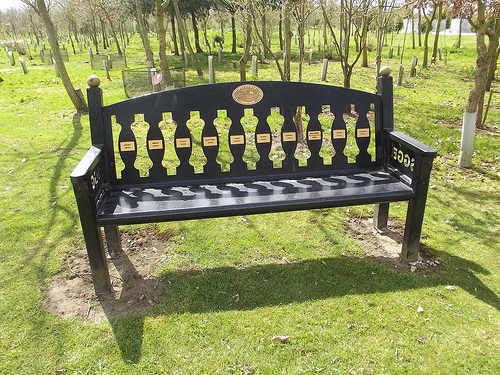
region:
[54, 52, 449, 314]
a bench on a field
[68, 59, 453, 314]
bench is black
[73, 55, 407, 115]
bench has two balls on restback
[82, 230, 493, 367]
shadow of a bench on the grass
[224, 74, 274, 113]
a plaque on top of restback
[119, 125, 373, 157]
small plaques on bench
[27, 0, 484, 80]
plants behind a bench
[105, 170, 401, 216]
shadows on bench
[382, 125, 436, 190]
right armrest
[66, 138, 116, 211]
right armrest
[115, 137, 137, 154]
plague on the bench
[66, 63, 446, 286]
bench with plagues on it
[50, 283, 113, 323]
patch of dirt on the ground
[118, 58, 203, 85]
fence around the tree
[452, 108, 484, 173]
white tube around tree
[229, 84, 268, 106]
gold plague on the bench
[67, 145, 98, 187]
arm of the bench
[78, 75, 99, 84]
white knob on the bench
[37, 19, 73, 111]
tree trunk attached to the tree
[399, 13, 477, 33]
white fence in the background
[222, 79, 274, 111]
A label on a bench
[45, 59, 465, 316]
a wooden bench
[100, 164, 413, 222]
the seating area of the bench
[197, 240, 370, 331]
grass below the bench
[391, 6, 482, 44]
a wooden structure in the background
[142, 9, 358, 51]
some trees in the background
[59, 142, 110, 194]
the right arm of the bench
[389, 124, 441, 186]
the left arm of the bench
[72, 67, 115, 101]
a decorative wooden ball atop the bench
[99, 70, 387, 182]
the back of the bench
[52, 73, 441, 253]
black wooden bench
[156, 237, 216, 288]
short green and brown grass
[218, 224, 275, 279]
short green and brown grass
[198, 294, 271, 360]
short green and brown grass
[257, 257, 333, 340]
short green and brown grass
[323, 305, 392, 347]
short green and brown grass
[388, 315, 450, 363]
short green and brown grass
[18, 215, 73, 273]
short green and brown grass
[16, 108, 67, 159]
short green and brown grass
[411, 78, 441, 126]
short green and brown grass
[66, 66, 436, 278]
a black bench in the park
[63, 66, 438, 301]
a black and gold bench in the park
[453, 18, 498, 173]
a brown tree trunk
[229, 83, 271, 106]
a gold symbol on the bench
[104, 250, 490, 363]
a shadow under the bench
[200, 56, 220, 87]
white concrete post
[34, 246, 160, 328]
dirt under the bench leg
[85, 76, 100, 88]
brass knobs on a bench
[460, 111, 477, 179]
white pip around tree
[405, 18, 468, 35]
white buildings in distance